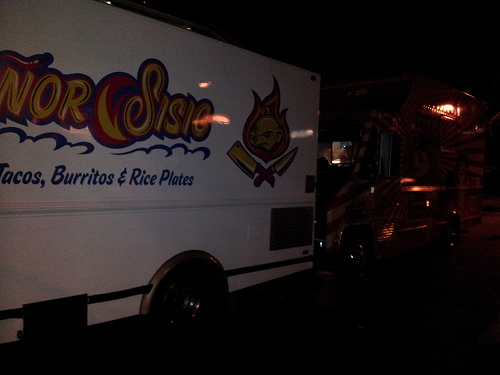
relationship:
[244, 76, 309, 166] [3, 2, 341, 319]
fire symbol on truck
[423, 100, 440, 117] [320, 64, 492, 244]
light reflection on food truck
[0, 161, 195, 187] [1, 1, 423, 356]
blue letter on bus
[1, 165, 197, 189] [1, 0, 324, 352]
blue letter on bus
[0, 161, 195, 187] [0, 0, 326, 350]
blue letter on bus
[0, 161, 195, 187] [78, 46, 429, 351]
blue letter on bus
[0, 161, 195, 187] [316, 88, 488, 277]
blue letter on bus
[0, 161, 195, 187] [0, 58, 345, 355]
blue letter on bus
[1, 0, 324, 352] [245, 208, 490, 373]
bus parked on street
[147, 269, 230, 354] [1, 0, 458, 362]
wheel on trailer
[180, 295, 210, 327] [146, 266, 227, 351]
rim of wheel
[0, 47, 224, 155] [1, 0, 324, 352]
logo on side of bus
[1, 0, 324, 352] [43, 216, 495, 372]
bus parked on street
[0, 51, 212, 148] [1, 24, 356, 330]
logo on side of truck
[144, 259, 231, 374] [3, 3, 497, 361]
wheel on truck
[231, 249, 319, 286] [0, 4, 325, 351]
stripe on bottom of truck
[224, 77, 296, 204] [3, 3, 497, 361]
image truck on side of truck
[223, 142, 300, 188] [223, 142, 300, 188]
image of image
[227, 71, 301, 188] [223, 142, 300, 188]
image of image